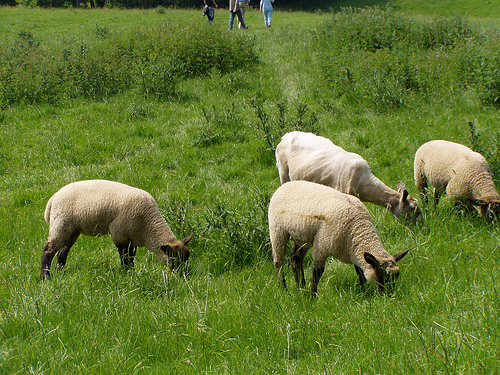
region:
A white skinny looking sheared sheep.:
[276, 129, 423, 226]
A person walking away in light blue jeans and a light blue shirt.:
[257, 0, 274, 28]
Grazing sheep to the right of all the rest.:
[413, 137, 499, 221]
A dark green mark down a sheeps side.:
[278, 208, 325, 220]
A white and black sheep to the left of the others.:
[40, 178, 192, 278]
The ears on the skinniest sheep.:
[396, 179, 408, 204]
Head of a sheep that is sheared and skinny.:
[399, 189, 424, 234]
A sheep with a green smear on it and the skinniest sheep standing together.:
[267, 133, 425, 296]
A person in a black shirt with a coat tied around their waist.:
[203, 0, 218, 22]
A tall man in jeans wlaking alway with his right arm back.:
[226, 0, 248, 30]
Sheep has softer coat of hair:
[263, 123, 375, 192]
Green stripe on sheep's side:
[275, 205, 330, 228]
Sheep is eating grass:
[362, 249, 409, 301]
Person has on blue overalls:
[256, 0, 276, 29]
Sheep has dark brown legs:
[33, 239, 140, 279]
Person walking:
[228, 2, 250, 34]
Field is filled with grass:
[2, 7, 495, 130]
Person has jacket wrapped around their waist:
[201, 3, 216, 21]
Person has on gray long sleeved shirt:
[228, 2, 243, 12]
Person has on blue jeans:
[225, 10, 248, 32]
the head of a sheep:
[360, 219, 459, 305]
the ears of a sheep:
[342, 222, 425, 293]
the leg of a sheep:
[298, 227, 336, 304]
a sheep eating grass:
[291, 202, 465, 353]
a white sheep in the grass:
[241, 180, 413, 318]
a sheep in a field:
[26, 122, 274, 267]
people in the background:
[196, 0, 291, 64]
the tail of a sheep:
[29, 165, 86, 233]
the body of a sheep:
[38, 175, 230, 335]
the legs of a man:
[221, 5, 257, 32]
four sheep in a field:
[34, 111, 493, 343]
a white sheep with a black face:
[266, 217, 420, 322]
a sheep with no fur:
[260, 127, 392, 184]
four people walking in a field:
[191, 0, 288, 28]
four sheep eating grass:
[39, 110, 484, 317]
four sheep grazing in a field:
[51, 116, 476, 326]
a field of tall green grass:
[23, 14, 462, 124]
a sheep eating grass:
[12, 180, 227, 305]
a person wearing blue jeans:
[222, 6, 247, 31]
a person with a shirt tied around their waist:
[197, 0, 222, 22]